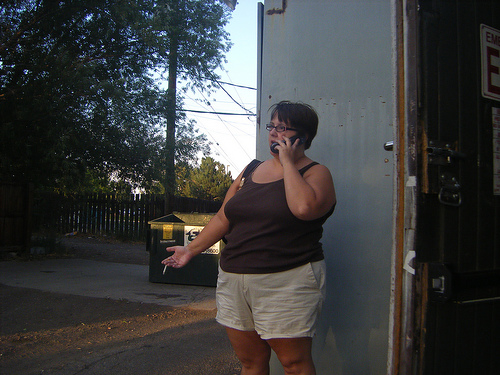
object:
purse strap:
[237, 159, 263, 181]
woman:
[162, 100, 337, 374]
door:
[388, 0, 500, 372]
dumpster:
[143, 210, 223, 289]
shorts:
[213, 249, 328, 341]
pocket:
[298, 262, 323, 295]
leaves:
[80, 321, 87, 327]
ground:
[0, 257, 241, 375]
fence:
[51, 183, 231, 245]